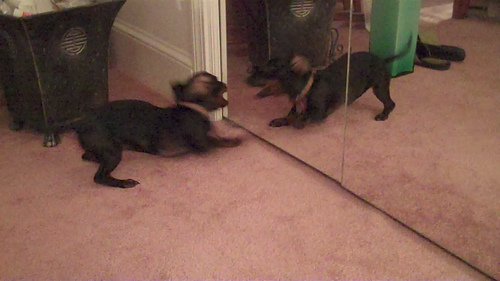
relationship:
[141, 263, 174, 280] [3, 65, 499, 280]
spot on carpet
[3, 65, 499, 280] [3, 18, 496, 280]
carpet on floor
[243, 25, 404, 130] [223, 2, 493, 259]
reflection in mirror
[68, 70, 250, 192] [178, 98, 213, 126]
dog has collar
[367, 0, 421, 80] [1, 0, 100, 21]
container for trash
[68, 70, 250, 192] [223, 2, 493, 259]
dog in front of mirror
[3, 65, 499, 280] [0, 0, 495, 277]
carpet in room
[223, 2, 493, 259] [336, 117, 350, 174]
mirror has line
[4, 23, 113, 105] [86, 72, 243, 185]
furniture next to dog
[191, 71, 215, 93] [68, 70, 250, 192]
ear of dog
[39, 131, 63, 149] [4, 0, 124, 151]
foot of drawer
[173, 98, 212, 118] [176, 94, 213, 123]
collar around neck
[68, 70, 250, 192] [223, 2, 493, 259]
dog in mirror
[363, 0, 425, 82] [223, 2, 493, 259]
column reflected mirror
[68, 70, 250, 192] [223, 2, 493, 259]
dog playing with mirror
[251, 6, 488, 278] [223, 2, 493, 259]
door covered with mirror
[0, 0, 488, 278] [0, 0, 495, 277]
door in a room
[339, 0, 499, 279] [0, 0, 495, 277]
door in a room